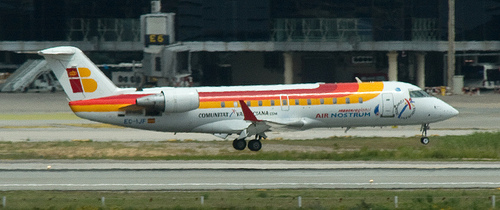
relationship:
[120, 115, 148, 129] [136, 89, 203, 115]
ec-uf under engine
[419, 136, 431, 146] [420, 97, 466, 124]
wheel under nose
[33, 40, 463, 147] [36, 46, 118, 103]
plane has tail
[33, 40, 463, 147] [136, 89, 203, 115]
plane has engine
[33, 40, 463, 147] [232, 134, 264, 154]
plane has landing gear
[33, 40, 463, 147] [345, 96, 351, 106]
plane has window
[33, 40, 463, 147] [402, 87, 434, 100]
plane has window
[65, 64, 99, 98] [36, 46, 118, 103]
symbol on tail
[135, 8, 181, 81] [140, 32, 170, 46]
sign says e6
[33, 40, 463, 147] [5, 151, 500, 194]
plane landing on runway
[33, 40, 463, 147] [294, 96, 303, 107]
plane has window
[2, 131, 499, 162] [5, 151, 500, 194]
grass near runway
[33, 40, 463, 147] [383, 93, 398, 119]
plane has door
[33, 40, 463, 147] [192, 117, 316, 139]
plane has wing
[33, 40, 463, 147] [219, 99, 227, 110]
plane has window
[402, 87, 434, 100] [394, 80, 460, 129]
window on front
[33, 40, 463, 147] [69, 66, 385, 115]
plane has colors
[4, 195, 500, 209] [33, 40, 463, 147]
fence near plane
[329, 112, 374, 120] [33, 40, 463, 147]
logo on plane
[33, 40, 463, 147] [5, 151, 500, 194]
plane taking off from runway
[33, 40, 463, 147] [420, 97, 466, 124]
plane has nose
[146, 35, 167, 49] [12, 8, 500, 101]
letters in distance